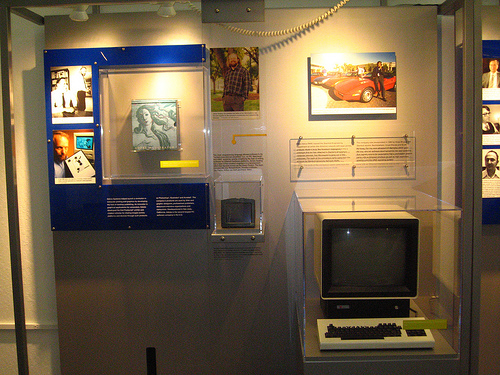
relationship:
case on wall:
[103, 57, 224, 182] [38, 21, 448, 357]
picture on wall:
[54, 70, 99, 123] [38, 21, 448, 357]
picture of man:
[54, 70, 99, 123] [216, 50, 278, 117]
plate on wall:
[214, 193, 270, 238] [38, 21, 448, 357]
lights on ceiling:
[71, 8, 182, 32] [44, 6, 439, 36]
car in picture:
[332, 70, 400, 120] [54, 70, 99, 123]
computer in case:
[310, 210, 449, 355] [103, 57, 224, 182]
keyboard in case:
[321, 305, 427, 365] [103, 57, 224, 182]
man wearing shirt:
[216, 50, 278, 117] [224, 70, 258, 101]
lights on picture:
[71, 8, 182, 32] [54, 70, 99, 123]